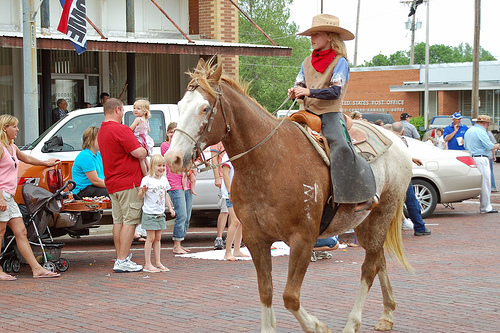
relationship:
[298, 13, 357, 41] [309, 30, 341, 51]
cowboy hat on head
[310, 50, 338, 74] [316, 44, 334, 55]
bandana around neck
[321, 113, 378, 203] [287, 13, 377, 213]
chap on leg of a girl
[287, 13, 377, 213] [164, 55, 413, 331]
girl riding a horse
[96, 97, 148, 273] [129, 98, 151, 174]
man holding child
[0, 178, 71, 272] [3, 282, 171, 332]
stroller on ground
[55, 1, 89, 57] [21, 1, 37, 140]
flag hanging down from a pole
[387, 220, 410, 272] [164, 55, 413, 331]
blond hair of a horse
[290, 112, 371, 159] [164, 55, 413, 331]
saddle on top of a horse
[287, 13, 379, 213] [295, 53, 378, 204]
girl wearing a cowboy outfit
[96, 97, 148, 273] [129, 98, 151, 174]
man holding little girl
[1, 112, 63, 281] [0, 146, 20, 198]
woman wearing a tank top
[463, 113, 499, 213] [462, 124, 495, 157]
man wearing a shirt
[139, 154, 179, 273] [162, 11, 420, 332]
girl watching a parade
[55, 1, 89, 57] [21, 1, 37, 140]
welcome flag on pole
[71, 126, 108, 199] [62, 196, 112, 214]
woman sitting in truck bed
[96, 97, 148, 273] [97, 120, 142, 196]
man wearing a shirt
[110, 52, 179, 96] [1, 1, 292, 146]
window of a building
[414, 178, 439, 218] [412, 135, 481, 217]
tire of a car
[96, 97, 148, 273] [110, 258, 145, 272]
man wearing tennis shoe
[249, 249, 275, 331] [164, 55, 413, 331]
leg of a horse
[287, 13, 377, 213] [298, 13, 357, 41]
girl wearing a cowboy hat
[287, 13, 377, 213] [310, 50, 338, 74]
girl wearing a handkerchief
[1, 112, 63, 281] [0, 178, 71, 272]
woman next to stroller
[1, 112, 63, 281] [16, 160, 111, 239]
woman leaning on an car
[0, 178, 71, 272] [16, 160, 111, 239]
stroller next to an orange car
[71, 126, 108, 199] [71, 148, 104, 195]
person wearing a top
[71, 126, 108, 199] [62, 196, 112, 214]
person sitting on top of a truck bed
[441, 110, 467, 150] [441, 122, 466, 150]
man in a blue shirt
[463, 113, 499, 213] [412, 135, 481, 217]
man near a car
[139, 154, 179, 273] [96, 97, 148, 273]
young girl next to a man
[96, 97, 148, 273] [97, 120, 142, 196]
man in a shirt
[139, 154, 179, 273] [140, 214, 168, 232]
young girl wearing a skirt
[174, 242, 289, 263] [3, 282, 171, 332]
blanket on ground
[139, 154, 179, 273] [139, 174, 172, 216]
young girl in a shirt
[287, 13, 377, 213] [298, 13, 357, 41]
girl with a cowboy hat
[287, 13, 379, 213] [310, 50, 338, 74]
girl with a bandana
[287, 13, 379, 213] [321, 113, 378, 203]
girl with a chap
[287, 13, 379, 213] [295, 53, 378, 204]
girl wearing western clothing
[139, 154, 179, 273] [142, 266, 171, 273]
blonde girl wearing flip flops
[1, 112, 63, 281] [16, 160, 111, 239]
blonde woman leaning on an truck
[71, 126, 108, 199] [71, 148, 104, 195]
woman wearing shirt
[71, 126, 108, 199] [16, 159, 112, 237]
woman sitting on an orange truck